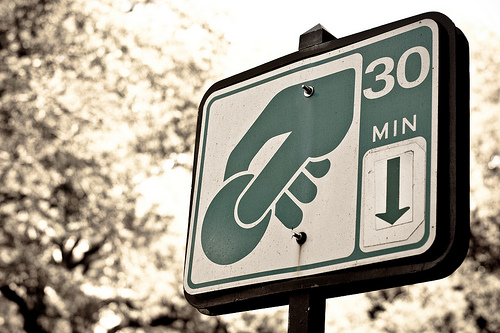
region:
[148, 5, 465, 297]
a sign on a pole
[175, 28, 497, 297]
a sign on a metal pole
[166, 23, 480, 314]
a street sign on a pole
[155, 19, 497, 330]
a street sign on a metal pole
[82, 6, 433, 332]
a pole with a sign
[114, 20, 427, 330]
a pole with a street sign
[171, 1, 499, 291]
a green and white sign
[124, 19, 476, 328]
a green and white street sign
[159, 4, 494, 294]
green and white sign on a pole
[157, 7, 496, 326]
green and white sign on a metal pole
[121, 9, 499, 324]
A SIGN ON A POLE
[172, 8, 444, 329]
a green street sign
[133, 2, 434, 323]
a green street sign on a metal pole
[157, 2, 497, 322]
a green sign on a pole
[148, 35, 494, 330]
a sign with 30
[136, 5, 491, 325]
a sign with an arrow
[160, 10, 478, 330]
a sign with a hand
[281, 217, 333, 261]
Small screw in sign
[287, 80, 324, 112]
Small screw in sign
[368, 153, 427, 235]
Green arrow pointing down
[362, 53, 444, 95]
White numbers with green background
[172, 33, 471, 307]
Green and white street sign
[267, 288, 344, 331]
Black colored pole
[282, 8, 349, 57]
Black colored pole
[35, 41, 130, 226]
Blurry black trees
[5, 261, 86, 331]
Blurry black trees in background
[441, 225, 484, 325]
Blurry black trees in background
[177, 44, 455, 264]
sign in the air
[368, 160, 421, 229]
arrow that is pointing down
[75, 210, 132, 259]
white flowers on tree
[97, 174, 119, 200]
white flowers on tree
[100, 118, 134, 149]
white flowers on tree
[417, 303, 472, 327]
white flowers on tree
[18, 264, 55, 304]
white flowers on tree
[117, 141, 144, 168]
white flowers on tree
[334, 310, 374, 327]
white flowers on tree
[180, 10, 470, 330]
Thirty minute parking only sign.